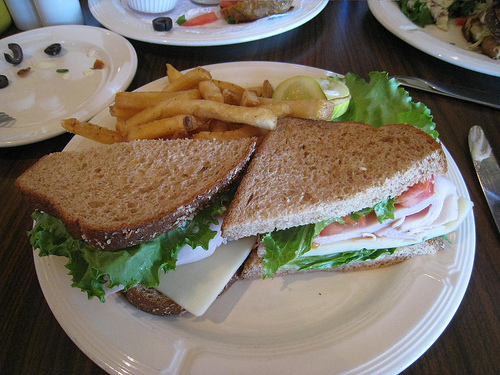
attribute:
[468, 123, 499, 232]
knife — shiny, silver, dirty, a section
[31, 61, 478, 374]
plate — white, round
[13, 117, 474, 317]
sandwich — cut in half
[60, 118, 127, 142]
french fry — crispy, golden, part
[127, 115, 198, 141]
french fry — crispy, golden, part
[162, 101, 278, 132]
french fry — crispy, golden, part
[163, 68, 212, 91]
french fry — crispy, golden, part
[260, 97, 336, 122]
french fry — crispy, golden, part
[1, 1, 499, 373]
table — wooden, brown, a section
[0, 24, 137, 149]
plate — used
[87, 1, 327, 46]
plate — white, edge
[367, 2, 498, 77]
plate — white, section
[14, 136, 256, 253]
bread — wheat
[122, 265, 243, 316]
bread — wheat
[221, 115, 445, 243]
bread — wheat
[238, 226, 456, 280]
bread — wheat, a section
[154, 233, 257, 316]
cheese — white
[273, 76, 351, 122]
pickle — green, a part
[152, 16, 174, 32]
olive — piece